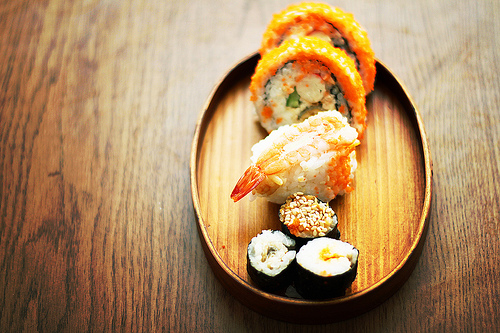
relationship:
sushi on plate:
[248, 230, 296, 295] [191, 50, 434, 326]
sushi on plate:
[298, 239, 360, 300] [191, 50, 434, 326]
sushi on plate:
[278, 196, 340, 242] [191, 50, 434, 326]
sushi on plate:
[230, 109, 360, 207] [191, 50, 434, 326]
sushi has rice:
[230, 109, 360, 207] [271, 151, 358, 203]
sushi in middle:
[230, 109, 360, 207] [242, 127, 374, 212]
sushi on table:
[248, 230, 296, 295] [1, 0, 500, 333]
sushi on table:
[298, 239, 360, 300] [1, 0, 500, 333]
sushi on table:
[278, 196, 340, 242] [1, 0, 500, 333]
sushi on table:
[230, 109, 360, 207] [1, 0, 500, 333]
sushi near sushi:
[248, 230, 296, 295] [298, 239, 360, 300]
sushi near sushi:
[298, 239, 360, 300] [278, 196, 340, 242]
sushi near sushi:
[278, 196, 340, 242] [248, 230, 296, 295]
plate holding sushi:
[191, 50, 434, 326] [291, 235, 360, 300]